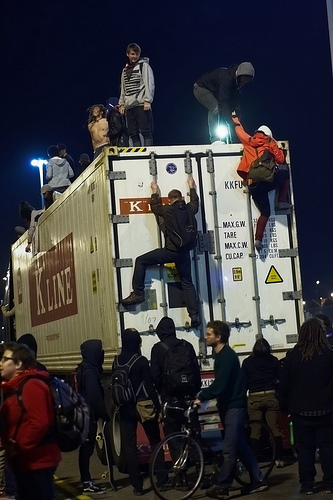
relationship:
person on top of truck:
[119, 42, 157, 147] [8, 138, 305, 415]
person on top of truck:
[190, 59, 255, 143] [8, 138, 305, 415]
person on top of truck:
[85, 101, 108, 161] [8, 138, 305, 415]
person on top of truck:
[40, 145, 71, 206] [8, 138, 305, 415]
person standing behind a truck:
[240, 339, 297, 467] [8, 138, 305, 415]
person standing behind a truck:
[280, 317, 332, 496] [8, 138, 305, 415]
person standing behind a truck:
[150, 315, 201, 468] [8, 138, 305, 415]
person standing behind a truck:
[107, 327, 174, 474] [8, 138, 305, 415]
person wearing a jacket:
[2, 341, 89, 498] [1, 367, 64, 472]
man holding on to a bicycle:
[193, 317, 270, 498] [146, 396, 281, 499]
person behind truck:
[240, 339, 297, 467] [8, 138, 305, 415]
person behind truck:
[280, 317, 332, 496] [8, 138, 305, 415]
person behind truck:
[150, 315, 201, 468] [8, 138, 305, 415]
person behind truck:
[107, 327, 174, 474] [8, 138, 305, 415]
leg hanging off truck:
[24, 208, 42, 254] [8, 138, 305, 415]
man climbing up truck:
[229, 112, 293, 252] [8, 138, 305, 415]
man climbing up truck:
[120, 178, 203, 328] [8, 138, 305, 415]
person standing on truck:
[119, 42, 157, 147] [8, 138, 305, 415]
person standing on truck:
[85, 101, 108, 161] [8, 138, 305, 415]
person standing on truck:
[40, 145, 71, 206] [8, 138, 305, 415]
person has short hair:
[119, 42, 157, 147] [124, 39, 142, 58]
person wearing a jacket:
[190, 59, 255, 143] [195, 65, 235, 125]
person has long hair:
[85, 101, 108, 161] [86, 101, 108, 123]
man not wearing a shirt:
[85, 101, 108, 161] [86, 120, 108, 145]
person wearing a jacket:
[190, 59, 255, 143] [1, 367, 64, 472]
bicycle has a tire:
[146, 396, 281, 499] [149, 433, 206, 499]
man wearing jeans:
[193, 317, 270, 498] [214, 409, 263, 486]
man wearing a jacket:
[229, 112, 293, 252] [229, 112, 286, 177]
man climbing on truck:
[229, 112, 293, 252] [8, 138, 305, 415]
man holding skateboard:
[79, 339, 117, 497] [92, 420, 117, 490]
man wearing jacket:
[229, 112, 293, 252] [229, 112, 286, 177]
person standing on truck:
[190, 59, 255, 143] [8, 138, 305, 415]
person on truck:
[190, 59, 255, 143] [8, 138, 305, 415]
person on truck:
[119, 42, 157, 147] [8, 138, 305, 415]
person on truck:
[85, 101, 108, 161] [8, 138, 305, 415]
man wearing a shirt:
[193, 317, 270, 498] [197, 347, 244, 411]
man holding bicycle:
[193, 317, 270, 498] [146, 396, 281, 499]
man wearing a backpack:
[120, 178, 203, 328] [162, 199, 204, 250]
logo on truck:
[29, 231, 81, 327] [8, 138, 305, 415]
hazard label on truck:
[264, 264, 283, 285] [8, 138, 305, 415]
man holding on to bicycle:
[193, 317, 270, 498] [146, 396, 281, 499]